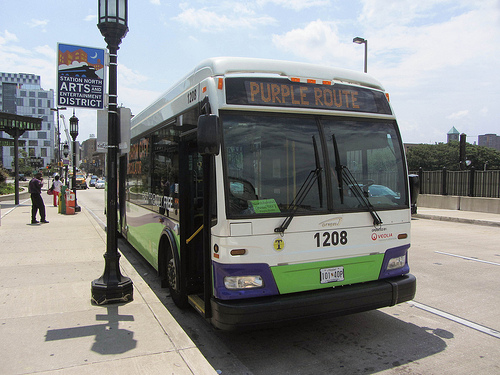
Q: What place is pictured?
A: It is a city.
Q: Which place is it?
A: It is a city.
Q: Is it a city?
A: Yes, it is a city.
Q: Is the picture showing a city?
A: Yes, it is showing a city.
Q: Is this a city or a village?
A: It is a city.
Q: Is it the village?
A: No, it is the city.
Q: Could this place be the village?
A: No, it is the city.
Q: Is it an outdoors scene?
A: Yes, it is outdoors.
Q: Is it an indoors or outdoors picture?
A: It is outdoors.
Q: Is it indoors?
A: No, it is outdoors.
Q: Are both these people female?
A: No, they are both male and female.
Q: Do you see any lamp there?
A: Yes, there is a lamp.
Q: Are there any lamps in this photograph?
A: Yes, there is a lamp.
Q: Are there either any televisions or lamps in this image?
A: Yes, there is a lamp.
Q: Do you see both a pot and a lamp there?
A: No, there is a lamp but no pots.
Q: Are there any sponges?
A: No, there are no sponges.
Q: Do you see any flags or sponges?
A: No, there are no sponges or flags.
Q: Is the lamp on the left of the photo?
A: Yes, the lamp is on the left of the image.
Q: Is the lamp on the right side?
A: No, the lamp is on the left of the image.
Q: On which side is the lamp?
A: The lamp is on the left of the image.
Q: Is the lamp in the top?
A: Yes, the lamp is in the top of the image.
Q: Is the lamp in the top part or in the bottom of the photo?
A: The lamp is in the top of the image.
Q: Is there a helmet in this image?
A: No, there are no helmets.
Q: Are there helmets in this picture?
A: No, there are no helmets.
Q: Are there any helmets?
A: No, there are no helmets.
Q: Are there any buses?
A: Yes, there is a bus.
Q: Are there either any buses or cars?
A: Yes, there is a bus.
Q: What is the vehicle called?
A: The vehicle is a bus.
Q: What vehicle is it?
A: The vehicle is a bus.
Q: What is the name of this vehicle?
A: That is a bus.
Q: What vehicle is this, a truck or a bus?
A: That is a bus.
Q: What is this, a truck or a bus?
A: This is a bus.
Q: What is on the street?
A: The bus is on the street.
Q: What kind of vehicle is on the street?
A: The vehicle is a bus.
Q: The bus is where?
A: The bus is on the street.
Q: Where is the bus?
A: The bus is on the street.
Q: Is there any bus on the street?
A: Yes, there is a bus on the street.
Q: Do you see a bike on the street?
A: No, there is a bus on the street.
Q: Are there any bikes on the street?
A: No, there is a bus on the street.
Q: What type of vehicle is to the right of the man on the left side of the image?
A: The vehicle is a bus.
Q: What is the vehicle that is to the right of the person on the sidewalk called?
A: The vehicle is a bus.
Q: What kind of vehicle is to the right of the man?
A: The vehicle is a bus.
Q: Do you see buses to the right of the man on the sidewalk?
A: Yes, there is a bus to the right of the man.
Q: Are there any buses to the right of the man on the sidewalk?
A: Yes, there is a bus to the right of the man.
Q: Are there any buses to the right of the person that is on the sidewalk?
A: Yes, there is a bus to the right of the man.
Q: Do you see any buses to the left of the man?
A: No, the bus is to the right of the man.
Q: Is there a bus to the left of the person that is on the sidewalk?
A: No, the bus is to the right of the man.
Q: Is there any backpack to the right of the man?
A: No, there is a bus to the right of the man.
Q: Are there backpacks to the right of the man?
A: No, there is a bus to the right of the man.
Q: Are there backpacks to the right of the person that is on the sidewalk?
A: No, there is a bus to the right of the man.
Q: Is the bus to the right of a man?
A: Yes, the bus is to the right of a man.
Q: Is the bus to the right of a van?
A: No, the bus is to the right of a man.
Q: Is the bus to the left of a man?
A: No, the bus is to the right of a man.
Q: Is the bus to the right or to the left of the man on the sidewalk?
A: The bus is to the right of the man.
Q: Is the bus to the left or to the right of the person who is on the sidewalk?
A: The bus is to the right of the man.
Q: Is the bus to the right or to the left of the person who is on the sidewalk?
A: The bus is to the right of the man.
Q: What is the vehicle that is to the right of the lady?
A: The vehicle is a bus.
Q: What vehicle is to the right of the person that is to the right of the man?
A: The vehicle is a bus.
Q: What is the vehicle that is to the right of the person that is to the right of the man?
A: The vehicle is a bus.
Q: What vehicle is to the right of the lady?
A: The vehicle is a bus.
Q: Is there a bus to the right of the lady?
A: Yes, there is a bus to the right of the lady.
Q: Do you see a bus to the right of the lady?
A: Yes, there is a bus to the right of the lady.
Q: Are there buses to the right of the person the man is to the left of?
A: Yes, there is a bus to the right of the lady.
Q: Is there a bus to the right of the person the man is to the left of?
A: Yes, there is a bus to the right of the lady.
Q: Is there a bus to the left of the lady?
A: No, the bus is to the right of the lady.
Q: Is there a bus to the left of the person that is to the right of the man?
A: No, the bus is to the right of the lady.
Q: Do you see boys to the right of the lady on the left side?
A: No, there is a bus to the right of the lady.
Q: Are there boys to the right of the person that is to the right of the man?
A: No, there is a bus to the right of the lady.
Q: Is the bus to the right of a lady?
A: Yes, the bus is to the right of a lady.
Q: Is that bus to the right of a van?
A: No, the bus is to the right of a lady.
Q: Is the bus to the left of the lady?
A: No, the bus is to the right of the lady.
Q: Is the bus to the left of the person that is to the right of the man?
A: No, the bus is to the right of the lady.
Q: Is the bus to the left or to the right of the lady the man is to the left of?
A: The bus is to the right of the lady.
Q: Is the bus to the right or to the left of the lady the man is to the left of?
A: The bus is to the right of the lady.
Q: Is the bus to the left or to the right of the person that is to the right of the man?
A: The bus is to the right of the lady.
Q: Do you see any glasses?
A: No, there are no glasses.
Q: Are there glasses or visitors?
A: No, there are no glasses or visitors.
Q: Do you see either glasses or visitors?
A: No, there are no glasses or visitors.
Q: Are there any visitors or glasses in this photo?
A: No, there are no glasses or visitors.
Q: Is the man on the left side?
A: Yes, the man is on the left of the image.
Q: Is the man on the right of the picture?
A: No, the man is on the left of the image.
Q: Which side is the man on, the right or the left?
A: The man is on the left of the image.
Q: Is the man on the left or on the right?
A: The man is on the left of the image.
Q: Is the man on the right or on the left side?
A: The man is on the left of the image.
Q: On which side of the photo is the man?
A: The man is on the left of the image.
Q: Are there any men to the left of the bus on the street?
A: Yes, there is a man to the left of the bus.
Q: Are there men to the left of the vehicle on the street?
A: Yes, there is a man to the left of the bus.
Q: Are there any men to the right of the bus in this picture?
A: No, the man is to the left of the bus.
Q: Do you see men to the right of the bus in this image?
A: No, the man is to the left of the bus.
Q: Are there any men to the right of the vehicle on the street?
A: No, the man is to the left of the bus.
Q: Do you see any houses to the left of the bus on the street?
A: No, there is a man to the left of the bus.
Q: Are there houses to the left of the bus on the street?
A: No, there is a man to the left of the bus.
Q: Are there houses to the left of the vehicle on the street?
A: No, there is a man to the left of the bus.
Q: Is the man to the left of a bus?
A: Yes, the man is to the left of a bus.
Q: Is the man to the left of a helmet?
A: No, the man is to the left of a bus.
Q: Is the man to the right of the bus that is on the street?
A: No, the man is to the left of the bus.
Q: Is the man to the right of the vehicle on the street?
A: No, the man is to the left of the bus.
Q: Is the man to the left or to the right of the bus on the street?
A: The man is to the left of the bus.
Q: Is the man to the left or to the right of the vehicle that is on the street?
A: The man is to the left of the bus.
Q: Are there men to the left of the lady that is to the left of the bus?
A: Yes, there is a man to the left of the lady.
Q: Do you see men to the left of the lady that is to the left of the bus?
A: Yes, there is a man to the left of the lady.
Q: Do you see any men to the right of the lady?
A: No, the man is to the left of the lady.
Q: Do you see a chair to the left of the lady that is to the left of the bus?
A: No, there is a man to the left of the lady.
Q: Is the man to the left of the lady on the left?
A: Yes, the man is to the left of the lady.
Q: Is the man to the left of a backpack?
A: No, the man is to the left of the lady.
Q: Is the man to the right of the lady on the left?
A: No, the man is to the left of the lady.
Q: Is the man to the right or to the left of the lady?
A: The man is to the left of the lady.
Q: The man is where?
A: The man is on the sidewalk.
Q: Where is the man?
A: The man is on the sidewalk.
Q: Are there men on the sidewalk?
A: Yes, there is a man on the sidewalk.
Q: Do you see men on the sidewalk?
A: Yes, there is a man on the sidewalk.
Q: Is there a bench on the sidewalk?
A: No, there is a man on the sidewalk.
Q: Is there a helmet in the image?
A: No, there are no helmets.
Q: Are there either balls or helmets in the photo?
A: No, there are no helmets or balls.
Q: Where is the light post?
A: The light post is on the sidewalk.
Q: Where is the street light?
A: The light post is on the sidewalk.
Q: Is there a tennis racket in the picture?
A: No, there are no rackets.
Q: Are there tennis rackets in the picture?
A: No, there are no tennis rackets.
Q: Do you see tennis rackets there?
A: No, there are no tennis rackets.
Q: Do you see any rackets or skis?
A: No, there are no rackets or skis.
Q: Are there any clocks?
A: No, there are no clocks.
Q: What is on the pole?
A: The sign is on the pole.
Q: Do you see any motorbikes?
A: No, there are no motorbikes.